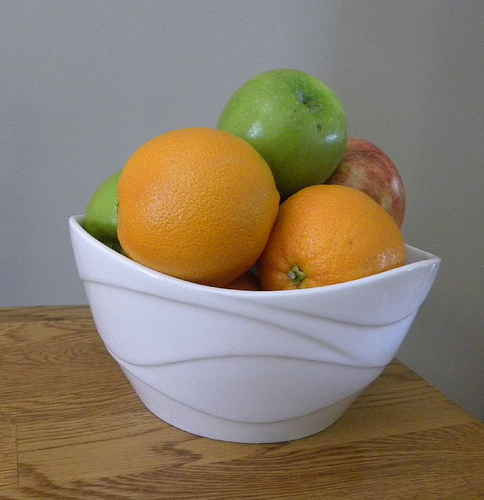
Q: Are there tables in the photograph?
A: Yes, there is a table.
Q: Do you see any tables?
A: Yes, there is a table.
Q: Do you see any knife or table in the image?
A: Yes, there is a table.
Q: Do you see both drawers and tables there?
A: No, there is a table but no drawers.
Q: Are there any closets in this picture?
A: No, there are no closets.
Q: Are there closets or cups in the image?
A: No, there are no closets or cups.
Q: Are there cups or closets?
A: No, there are no closets or cups.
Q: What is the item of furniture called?
A: The piece of furniture is a table.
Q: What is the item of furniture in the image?
A: The piece of furniture is a table.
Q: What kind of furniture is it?
A: The piece of furniture is a table.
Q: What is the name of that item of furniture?
A: This is a table.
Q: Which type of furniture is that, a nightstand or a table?
A: This is a table.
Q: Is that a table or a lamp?
A: That is a table.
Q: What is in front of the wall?
A: The table is in front of the wall.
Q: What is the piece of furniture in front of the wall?
A: The piece of furniture is a table.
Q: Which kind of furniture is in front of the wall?
A: The piece of furniture is a table.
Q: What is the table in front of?
A: The table is in front of the wall.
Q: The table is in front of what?
A: The table is in front of the wall.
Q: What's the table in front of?
A: The table is in front of the wall.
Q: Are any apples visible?
A: Yes, there is an apple.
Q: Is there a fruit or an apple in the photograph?
A: Yes, there is an apple.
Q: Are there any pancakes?
A: No, there are no pancakes.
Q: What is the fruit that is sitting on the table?
A: The fruit is an apple.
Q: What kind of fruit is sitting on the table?
A: The fruit is an apple.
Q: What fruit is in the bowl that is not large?
A: The fruit is an apple.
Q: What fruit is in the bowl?
A: The fruit is an apple.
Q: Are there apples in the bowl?
A: Yes, there is an apple in the bowl.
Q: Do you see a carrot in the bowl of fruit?
A: No, there is an apple in the bowl.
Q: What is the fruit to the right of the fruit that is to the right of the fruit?
A: The fruit is an apple.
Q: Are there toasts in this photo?
A: No, there are no toasts.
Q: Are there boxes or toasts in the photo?
A: No, there are no toasts or boxes.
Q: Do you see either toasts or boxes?
A: No, there are no toasts or boxes.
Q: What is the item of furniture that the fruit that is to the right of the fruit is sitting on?
A: The piece of furniture is a table.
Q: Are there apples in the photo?
A: Yes, there is an apple.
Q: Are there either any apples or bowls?
A: Yes, there is an apple.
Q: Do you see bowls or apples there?
A: Yes, there is an apple.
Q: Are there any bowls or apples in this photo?
A: Yes, there is an apple.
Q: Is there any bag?
A: No, there are no bags.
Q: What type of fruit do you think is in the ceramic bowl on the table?
A: The fruit is an apple.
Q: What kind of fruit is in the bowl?
A: The fruit is an apple.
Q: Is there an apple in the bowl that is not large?
A: Yes, there is an apple in the bowl.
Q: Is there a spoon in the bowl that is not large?
A: No, there is an apple in the bowl.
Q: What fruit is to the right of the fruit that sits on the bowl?
A: The fruit is an apple.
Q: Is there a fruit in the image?
A: Yes, there is a fruit.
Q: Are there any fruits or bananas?
A: Yes, there is a fruit.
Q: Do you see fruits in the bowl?
A: Yes, there is a fruit in the bowl.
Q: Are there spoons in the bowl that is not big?
A: No, there is a fruit in the bowl.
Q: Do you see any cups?
A: No, there are no cups.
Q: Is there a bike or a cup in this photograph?
A: No, there are no cups or bikes.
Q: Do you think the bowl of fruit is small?
A: Yes, the bowl is small.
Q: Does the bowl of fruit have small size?
A: Yes, the bowl is small.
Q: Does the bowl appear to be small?
A: Yes, the bowl is small.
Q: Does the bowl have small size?
A: Yes, the bowl is small.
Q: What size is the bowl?
A: The bowl is small.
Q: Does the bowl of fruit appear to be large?
A: No, the bowl is small.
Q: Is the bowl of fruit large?
A: No, the bowl is small.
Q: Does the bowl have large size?
A: No, the bowl is small.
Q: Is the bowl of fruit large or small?
A: The bowl is small.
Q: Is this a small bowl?
A: Yes, this is a small bowl.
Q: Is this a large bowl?
A: No, this is a small bowl.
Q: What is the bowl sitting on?
A: The bowl is sitting on the table.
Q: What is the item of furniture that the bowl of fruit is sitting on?
A: The piece of furniture is a table.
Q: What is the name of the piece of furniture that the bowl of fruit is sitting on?
A: The piece of furniture is a table.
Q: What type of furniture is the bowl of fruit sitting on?
A: The bowl is sitting on the table.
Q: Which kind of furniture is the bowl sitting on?
A: The bowl is sitting on the table.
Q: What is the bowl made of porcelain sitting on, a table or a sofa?
A: The bowl is sitting on a table.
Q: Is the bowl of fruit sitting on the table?
A: Yes, the bowl is sitting on the table.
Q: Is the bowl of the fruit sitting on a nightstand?
A: No, the bowl is sitting on the table.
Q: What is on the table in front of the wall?
A: The bowl is on the table.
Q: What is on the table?
A: The bowl is on the table.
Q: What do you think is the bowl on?
A: The bowl is on the table.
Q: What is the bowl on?
A: The bowl is on the table.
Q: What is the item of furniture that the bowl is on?
A: The piece of furniture is a table.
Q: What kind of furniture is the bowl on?
A: The bowl is on the table.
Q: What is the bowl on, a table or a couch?
A: The bowl is on a table.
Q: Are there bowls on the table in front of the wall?
A: Yes, there is a bowl on the table.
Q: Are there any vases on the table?
A: No, there is a bowl on the table.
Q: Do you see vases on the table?
A: No, there is a bowl on the table.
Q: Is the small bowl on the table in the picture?
A: Yes, the bowl is on the table.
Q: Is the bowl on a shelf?
A: No, the bowl is on the table.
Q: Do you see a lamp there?
A: No, there are no lamps.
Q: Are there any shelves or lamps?
A: No, there are no lamps or shelves.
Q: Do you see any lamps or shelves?
A: No, there are no lamps or shelves.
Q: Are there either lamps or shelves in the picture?
A: No, there are no lamps or shelves.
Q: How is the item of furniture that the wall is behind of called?
A: The piece of furniture is a table.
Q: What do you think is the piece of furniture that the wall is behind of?
A: The piece of furniture is a table.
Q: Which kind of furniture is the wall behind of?
A: The wall is behind the table.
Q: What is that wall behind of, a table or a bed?
A: The wall is behind a table.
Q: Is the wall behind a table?
A: Yes, the wall is behind a table.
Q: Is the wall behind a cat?
A: No, the wall is behind a table.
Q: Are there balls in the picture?
A: No, there are no balls.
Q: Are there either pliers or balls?
A: No, there are no balls or pliers.